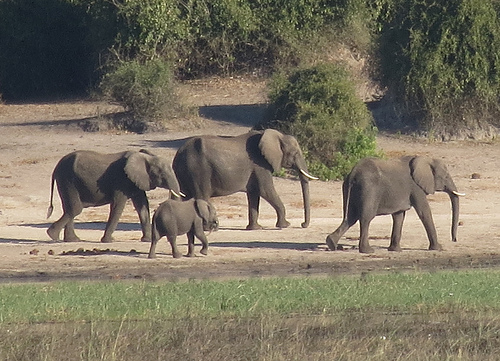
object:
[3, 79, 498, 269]
brown dirt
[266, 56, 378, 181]
bush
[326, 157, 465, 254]
elephant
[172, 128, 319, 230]
elephant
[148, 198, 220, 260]
baby elephant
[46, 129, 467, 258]
herd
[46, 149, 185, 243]
elephant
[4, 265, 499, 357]
grass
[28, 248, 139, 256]
pile